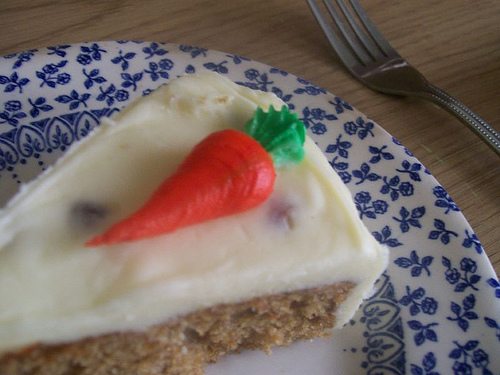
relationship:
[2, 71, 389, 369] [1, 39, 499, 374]
cake on dish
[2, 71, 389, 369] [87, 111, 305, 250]
cake has carrot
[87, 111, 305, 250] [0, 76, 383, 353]
carrot on top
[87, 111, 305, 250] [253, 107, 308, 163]
carrot has green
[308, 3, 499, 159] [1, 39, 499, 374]
fork by dish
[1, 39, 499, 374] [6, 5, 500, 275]
table on table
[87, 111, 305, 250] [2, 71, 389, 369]
carrot on cake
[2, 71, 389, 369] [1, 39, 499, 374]
cake on plate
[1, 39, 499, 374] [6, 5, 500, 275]
plate on table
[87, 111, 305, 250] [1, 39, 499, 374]
carrot on plate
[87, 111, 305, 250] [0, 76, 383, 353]
carrot made from icing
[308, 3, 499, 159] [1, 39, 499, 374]
fork near plate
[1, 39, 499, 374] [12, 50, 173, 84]
plate has a pattern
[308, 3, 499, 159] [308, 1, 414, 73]
fork has prongs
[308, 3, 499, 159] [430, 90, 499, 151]
fork has handle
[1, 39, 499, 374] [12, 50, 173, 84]
plate has a design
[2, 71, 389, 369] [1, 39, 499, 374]
cake sitting on dish